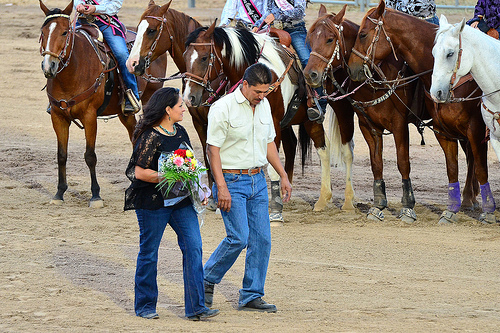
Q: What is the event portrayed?
A: A horse race.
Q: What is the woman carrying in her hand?
A: Flowers.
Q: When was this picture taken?
A: Daytime.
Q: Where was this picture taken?
A: At the rodeo.